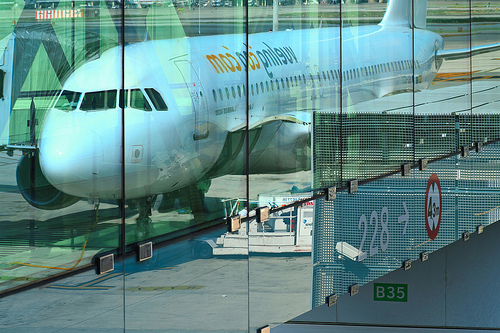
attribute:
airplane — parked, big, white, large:
[36, 0, 500, 240]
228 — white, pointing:
[347, 208, 404, 264]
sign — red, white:
[421, 171, 451, 241]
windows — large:
[124, 0, 252, 333]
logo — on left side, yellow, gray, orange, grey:
[203, 41, 303, 82]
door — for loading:
[173, 53, 209, 141]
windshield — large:
[79, 86, 119, 116]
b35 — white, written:
[370, 279, 412, 304]